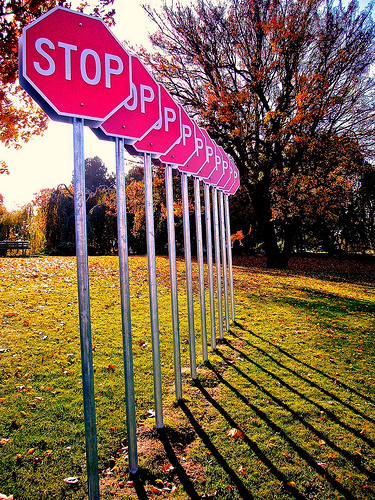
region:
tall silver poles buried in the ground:
[50, 117, 242, 494]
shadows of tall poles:
[126, 307, 374, 498]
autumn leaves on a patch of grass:
[2, 254, 68, 316]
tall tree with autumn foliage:
[127, 1, 359, 226]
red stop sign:
[23, 2, 138, 127]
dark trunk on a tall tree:
[245, 178, 309, 269]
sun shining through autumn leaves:
[0, 89, 49, 160]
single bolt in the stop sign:
[71, 17, 91, 34]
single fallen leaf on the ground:
[224, 424, 249, 445]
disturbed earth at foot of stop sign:
[141, 425, 182, 472]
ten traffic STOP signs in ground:
[18, 5, 241, 498]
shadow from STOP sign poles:
[132, 322, 374, 499]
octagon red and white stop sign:
[18, 7, 131, 127]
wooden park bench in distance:
[0, 241, 34, 258]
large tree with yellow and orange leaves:
[122, 0, 374, 268]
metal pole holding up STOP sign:
[72, 116, 101, 498]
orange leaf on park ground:
[225, 427, 246, 440]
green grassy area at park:
[0, 255, 374, 499]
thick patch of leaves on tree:
[253, 13, 309, 53]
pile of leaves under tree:
[287, 255, 373, 274]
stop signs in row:
[38, 19, 243, 171]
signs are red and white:
[44, 6, 247, 203]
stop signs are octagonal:
[37, 28, 232, 186]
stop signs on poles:
[43, 151, 263, 486]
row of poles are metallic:
[49, 148, 256, 470]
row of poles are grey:
[55, 132, 278, 473]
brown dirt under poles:
[97, 318, 248, 493]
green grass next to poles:
[251, 325, 364, 468]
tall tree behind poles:
[113, 19, 371, 225]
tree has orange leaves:
[116, 11, 351, 158]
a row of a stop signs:
[14, 6, 247, 480]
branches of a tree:
[303, 16, 339, 55]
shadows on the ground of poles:
[148, 323, 373, 497]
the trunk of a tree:
[246, 178, 305, 272]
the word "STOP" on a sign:
[19, 5, 136, 134]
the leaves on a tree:
[296, 179, 331, 218]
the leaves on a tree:
[37, 198, 63, 233]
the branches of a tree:
[163, 9, 211, 58]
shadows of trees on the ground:
[267, 263, 332, 313]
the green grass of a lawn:
[27, 323, 70, 391]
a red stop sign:
[26, 15, 126, 128]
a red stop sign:
[87, 34, 177, 171]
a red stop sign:
[133, 86, 208, 178]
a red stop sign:
[180, 103, 248, 164]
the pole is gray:
[54, 130, 108, 476]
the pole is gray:
[100, 139, 143, 449]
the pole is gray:
[136, 153, 175, 470]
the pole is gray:
[161, 166, 186, 426]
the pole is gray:
[174, 171, 222, 424]